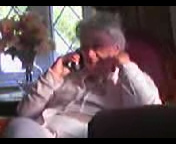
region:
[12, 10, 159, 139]
this is a person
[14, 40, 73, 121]
the hand of a person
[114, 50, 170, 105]
the hand of a person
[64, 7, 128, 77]
the head of a person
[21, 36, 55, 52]
this is a flower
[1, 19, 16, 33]
this is a flower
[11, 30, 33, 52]
this is a flower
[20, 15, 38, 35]
this is a flower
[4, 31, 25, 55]
this is a flower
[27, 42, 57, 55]
this is a flower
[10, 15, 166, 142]
man on the phone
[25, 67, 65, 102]
wrinkles on the sleeve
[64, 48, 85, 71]
phone lifted up to the face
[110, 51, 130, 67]
hand resting on the face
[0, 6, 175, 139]
the scene is blurry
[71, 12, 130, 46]
white hair on the head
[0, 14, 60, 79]
a bouquet of flowers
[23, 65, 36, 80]
narrow stems of the flowers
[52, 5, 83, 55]
black marks on the window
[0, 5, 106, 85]
windows on the wall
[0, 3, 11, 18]
pane of window glass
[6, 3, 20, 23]
pane of window glass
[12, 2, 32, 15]
pane of window glass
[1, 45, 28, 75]
pane of window glass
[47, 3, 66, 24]
pane of window glass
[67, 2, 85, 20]
pane of window glass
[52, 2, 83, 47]
pane of window glass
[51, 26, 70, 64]
pane of window glass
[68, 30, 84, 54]
pane of window glass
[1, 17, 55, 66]
Flower bouquet in the vase.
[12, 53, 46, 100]
Clear vase in the background.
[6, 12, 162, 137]
Woman sitting in the forefront.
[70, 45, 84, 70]
Telephone in the hand.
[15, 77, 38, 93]
White rocks in the vase.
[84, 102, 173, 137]
arm of the chair.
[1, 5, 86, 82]
Window in the house.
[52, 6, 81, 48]
Diamond shape on the window.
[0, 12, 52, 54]
Pink colored flowers.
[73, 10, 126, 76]
Gray hair on the woman.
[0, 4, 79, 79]
flowers in front of window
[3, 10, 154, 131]
woman seated in front of window and wall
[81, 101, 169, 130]
dark object in front of woman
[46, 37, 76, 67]
hand holding cellphone to face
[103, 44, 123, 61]
curled hand on side of face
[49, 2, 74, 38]
diamond pattern on window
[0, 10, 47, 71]
pink flowers on long stems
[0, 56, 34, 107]
glass vase on dark table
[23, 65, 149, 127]
shirt strings hanging down from neck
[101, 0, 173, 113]
wall painted a purplish red